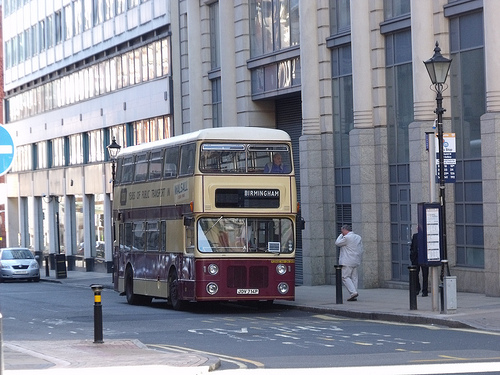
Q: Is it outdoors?
A: Yes, it is outdoors.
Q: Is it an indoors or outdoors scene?
A: It is outdoors.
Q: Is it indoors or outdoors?
A: It is outdoors.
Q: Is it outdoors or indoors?
A: It is outdoors.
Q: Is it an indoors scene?
A: No, it is outdoors.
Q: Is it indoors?
A: No, it is outdoors.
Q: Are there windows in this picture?
A: Yes, there is a window.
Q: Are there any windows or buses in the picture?
A: Yes, there is a window.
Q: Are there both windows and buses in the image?
A: Yes, there are both a window and a bus.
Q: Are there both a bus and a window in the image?
A: Yes, there are both a window and a bus.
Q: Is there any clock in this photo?
A: No, there are no clocks.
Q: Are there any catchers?
A: No, there are no catchers.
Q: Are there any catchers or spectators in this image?
A: No, there are no catchers or spectators.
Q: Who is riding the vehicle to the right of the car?
A: The man is riding the bus.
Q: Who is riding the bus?
A: The man is riding the bus.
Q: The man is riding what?
A: The man is riding the bus.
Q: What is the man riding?
A: The man is riding the bus.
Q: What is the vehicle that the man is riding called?
A: The vehicle is a bus.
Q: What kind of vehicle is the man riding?
A: The man is riding the bus.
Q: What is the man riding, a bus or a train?
A: The man is riding a bus.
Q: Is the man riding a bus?
A: Yes, the man is riding a bus.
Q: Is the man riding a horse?
A: No, the man is riding a bus.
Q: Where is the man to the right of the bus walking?
A: The man is walking on the street.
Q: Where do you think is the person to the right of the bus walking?
A: The man is walking on the street.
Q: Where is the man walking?
A: The man is walking on the street.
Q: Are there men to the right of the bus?
A: Yes, there is a man to the right of the bus.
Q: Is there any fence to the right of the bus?
A: No, there is a man to the right of the bus.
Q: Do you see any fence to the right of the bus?
A: No, there is a man to the right of the bus.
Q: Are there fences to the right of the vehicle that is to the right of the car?
A: No, there is a man to the right of the bus.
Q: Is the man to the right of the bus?
A: Yes, the man is to the right of the bus.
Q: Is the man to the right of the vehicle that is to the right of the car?
A: Yes, the man is to the right of the bus.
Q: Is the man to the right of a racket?
A: No, the man is to the right of the bus.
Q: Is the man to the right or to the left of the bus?
A: The man is to the right of the bus.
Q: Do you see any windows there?
A: Yes, there is a window.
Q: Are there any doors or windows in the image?
A: Yes, there is a window.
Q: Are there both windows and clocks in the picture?
A: No, there is a window but no clocks.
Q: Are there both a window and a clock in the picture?
A: No, there is a window but no clocks.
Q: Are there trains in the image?
A: No, there are no trains.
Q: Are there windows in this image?
A: Yes, there is a window.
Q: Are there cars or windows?
A: Yes, there is a window.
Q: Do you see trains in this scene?
A: No, there are no trains.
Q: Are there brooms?
A: No, there are no brooms.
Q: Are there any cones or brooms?
A: No, there are no brooms or cones.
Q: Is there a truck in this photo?
A: No, there are no trucks.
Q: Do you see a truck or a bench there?
A: No, there are no trucks or benches.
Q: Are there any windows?
A: Yes, there is a window.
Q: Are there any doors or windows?
A: Yes, there is a window.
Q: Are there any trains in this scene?
A: No, there are no trains.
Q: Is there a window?
A: Yes, there are windows.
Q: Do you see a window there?
A: Yes, there are windows.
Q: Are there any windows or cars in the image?
A: Yes, there are windows.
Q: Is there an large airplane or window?
A: Yes, there are large windows.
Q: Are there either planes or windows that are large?
A: Yes, the windows are large.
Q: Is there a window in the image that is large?
A: Yes, there are large windows.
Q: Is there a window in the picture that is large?
A: Yes, there are windows that are large.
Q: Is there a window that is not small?
A: Yes, there are large windows.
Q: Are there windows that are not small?
A: Yes, there are large windows.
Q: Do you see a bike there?
A: No, there are no bikes.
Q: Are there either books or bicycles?
A: No, there are no bicycles or books.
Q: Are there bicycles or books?
A: No, there are no bicycles or books.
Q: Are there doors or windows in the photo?
A: Yes, there is a window.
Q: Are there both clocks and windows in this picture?
A: No, there is a window but no clocks.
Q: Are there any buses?
A: Yes, there is a bus.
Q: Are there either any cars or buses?
A: Yes, there is a bus.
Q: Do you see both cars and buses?
A: Yes, there are both a bus and a car.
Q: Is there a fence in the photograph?
A: No, there are no fences.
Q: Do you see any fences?
A: No, there are no fences.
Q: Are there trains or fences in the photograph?
A: No, there are no fences or trains.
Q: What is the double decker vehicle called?
A: The vehicle is a bus.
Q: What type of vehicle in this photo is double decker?
A: The vehicle is a bus.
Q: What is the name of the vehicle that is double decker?
A: The vehicle is a bus.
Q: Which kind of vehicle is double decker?
A: The vehicle is a bus.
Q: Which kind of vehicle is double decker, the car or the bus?
A: The bus is double decker.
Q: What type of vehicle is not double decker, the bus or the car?
A: The car is not double decker.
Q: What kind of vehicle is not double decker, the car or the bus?
A: The car is not double decker.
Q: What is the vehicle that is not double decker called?
A: The vehicle is a car.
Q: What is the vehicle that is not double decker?
A: The vehicle is a car.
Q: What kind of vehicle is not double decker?
A: The vehicle is a car.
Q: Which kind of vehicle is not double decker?
A: The vehicle is a car.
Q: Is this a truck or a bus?
A: This is a bus.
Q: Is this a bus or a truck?
A: This is a bus.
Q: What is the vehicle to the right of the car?
A: The vehicle is a bus.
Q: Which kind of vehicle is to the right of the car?
A: The vehicle is a bus.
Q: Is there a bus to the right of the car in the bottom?
A: Yes, there is a bus to the right of the car.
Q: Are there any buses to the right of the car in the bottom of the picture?
A: Yes, there is a bus to the right of the car.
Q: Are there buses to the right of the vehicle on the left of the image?
A: Yes, there is a bus to the right of the car.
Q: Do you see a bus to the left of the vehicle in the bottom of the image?
A: No, the bus is to the right of the car.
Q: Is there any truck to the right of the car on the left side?
A: No, there is a bus to the right of the car.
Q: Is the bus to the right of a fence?
A: No, the bus is to the right of the car.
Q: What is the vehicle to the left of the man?
A: The vehicle is a bus.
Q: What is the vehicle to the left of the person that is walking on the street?
A: The vehicle is a bus.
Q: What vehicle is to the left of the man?
A: The vehicle is a bus.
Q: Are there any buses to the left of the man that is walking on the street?
A: Yes, there is a bus to the left of the man.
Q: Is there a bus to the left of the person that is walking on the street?
A: Yes, there is a bus to the left of the man.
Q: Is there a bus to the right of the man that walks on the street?
A: No, the bus is to the left of the man.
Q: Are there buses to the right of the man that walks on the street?
A: No, the bus is to the left of the man.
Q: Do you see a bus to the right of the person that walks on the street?
A: No, the bus is to the left of the man.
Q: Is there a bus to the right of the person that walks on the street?
A: No, the bus is to the left of the man.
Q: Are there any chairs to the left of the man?
A: No, there is a bus to the left of the man.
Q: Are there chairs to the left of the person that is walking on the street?
A: No, there is a bus to the left of the man.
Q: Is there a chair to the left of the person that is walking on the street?
A: No, there is a bus to the left of the man.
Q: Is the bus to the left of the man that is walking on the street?
A: Yes, the bus is to the left of the man.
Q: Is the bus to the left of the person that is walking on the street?
A: Yes, the bus is to the left of the man.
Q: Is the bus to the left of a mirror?
A: No, the bus is to the left of the man.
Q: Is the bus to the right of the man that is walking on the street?
A: No, the bus is to the left of the man.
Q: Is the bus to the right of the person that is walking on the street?
A: No, the bus is to the left of the man.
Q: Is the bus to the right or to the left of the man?
A: The bus is to the left of the man.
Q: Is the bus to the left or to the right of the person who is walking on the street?
A: The bus is to the left of the man.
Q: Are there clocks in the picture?
A: No, there are no clocks.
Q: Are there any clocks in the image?
A: No, there are no clocks.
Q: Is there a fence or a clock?
A: No, there are no clocks or fences.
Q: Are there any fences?
A: No, there are no fences.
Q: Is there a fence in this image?
A: No, there are no fences.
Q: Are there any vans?
A: No, there are no vans.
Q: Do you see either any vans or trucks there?
A: No, there are no vans or trucks.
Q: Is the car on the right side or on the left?
A: The car is on the left of the image.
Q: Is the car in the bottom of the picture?
A: Yes, the car is in the bottom of the image.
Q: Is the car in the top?
A: No, the car is in the bottom of the image.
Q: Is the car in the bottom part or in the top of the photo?
A: The car is in the bottom of the image.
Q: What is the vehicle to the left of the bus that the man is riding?
A: The vehicle is a car.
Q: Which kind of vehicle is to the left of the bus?
A: The vehicle is a car.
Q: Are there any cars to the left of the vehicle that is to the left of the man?
A: Yes, there is a car to the left of the bus.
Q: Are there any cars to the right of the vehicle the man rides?
A: No, the car is to the left of the bus.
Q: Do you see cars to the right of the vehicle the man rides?
A: No, the car is to the left of the bus.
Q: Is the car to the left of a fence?
A: No, the car is to the left of a bus.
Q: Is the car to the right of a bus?
A: No, the car is to the left of a bus.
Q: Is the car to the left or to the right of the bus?
A: The car is to the left of the bus.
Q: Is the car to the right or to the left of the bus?
A: The car is to the left of the bus.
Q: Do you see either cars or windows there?
A: Yes, there is a window.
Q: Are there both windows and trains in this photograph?
A: No, there is a window but no trains.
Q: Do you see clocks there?
A: No, there are no clocks.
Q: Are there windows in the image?
A: Yes, there is a window.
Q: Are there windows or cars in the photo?
A: Yes, there is a window.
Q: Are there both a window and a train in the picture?
A: No, there is a window but no trains.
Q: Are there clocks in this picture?
A: No, there are no clocks.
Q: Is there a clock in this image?
A: No, there are no clocks.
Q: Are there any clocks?
A: No, there are no clocks.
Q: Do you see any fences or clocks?
A: No, there are no clocks or fences.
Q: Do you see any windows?
A: Yes, there are windows.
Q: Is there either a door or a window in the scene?
A: Yes, there are windows.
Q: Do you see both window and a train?
A: No, there are windows but no trains.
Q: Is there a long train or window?
A: Yes, there are long windows.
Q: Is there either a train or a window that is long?
A: Yes, the windows are long.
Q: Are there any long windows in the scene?
A: Yes, there are long windows.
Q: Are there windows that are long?
A: Yes, there are windows that are long.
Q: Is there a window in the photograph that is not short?
A: Yes, there are long windows.